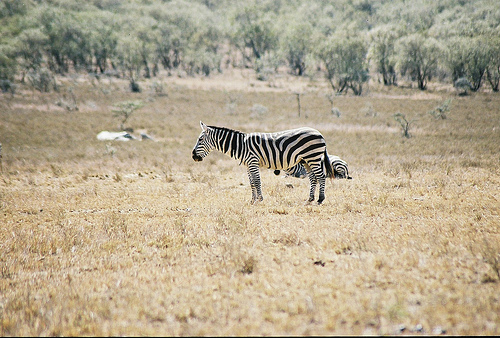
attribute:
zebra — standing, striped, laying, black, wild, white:
[191, 119, 336, 205]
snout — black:
[192, 152, 198, 160]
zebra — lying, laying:
[273, 158, 348, 178]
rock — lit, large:
[97, 130, 150, 143]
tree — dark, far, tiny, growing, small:
[316, 31, 369, 95]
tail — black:
[325, 150, 334, 178]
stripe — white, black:
[281, 131, 322, 171]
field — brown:
[0, 72, 500, 338]